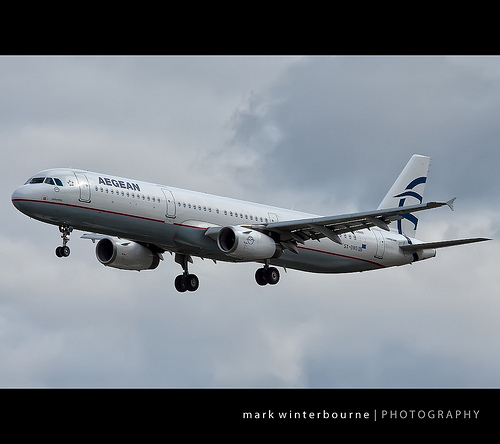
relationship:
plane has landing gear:
[9, 143, 493, 304] [172, 254, 203, 299]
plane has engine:
[9, 143, 493, 304] [87, 235, 164, 279]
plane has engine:
[9, 143, 493, 304] [211, 222, 286, 269]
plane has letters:
[9, 143, 493, 304] [95, 171, 143, 195]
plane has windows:
[9, 143, 493, 304] [92, 185, 163, 204]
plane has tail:
[9, 143, 493, 304] [375, 147, 433, 238]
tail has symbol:
[375, 147, 433, 238] [397, 172, 427, 238]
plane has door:
[9, 143, 493, 304] [71, 165, 95, 206]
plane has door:
[9, 143, 493, 304] [159, 183, 177, 220]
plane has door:
[9, 143, 493, 304] [373, 226, 386, 264]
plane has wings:
[9, 143, 493, 304] [263, 196, 457, 244]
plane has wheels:
[9, 143, 493, 304] [52, 242, 73, 259]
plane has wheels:
[9, 143, 493, 304] [255, 264, 279, 286]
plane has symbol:
[9, 143, 493, 304] [397, 172, 427, 238]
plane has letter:
[9, 143, 493, 304] [111, 177, 121, 189]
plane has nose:
[9, 143, 493, 304] [10, 185, 30, 211]